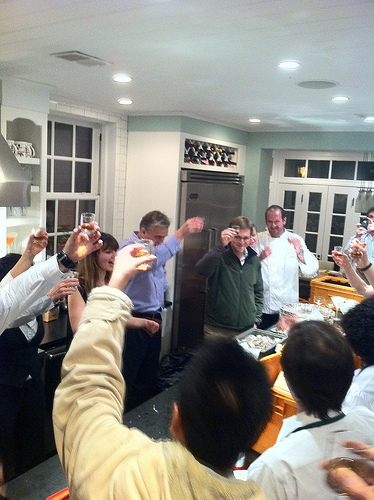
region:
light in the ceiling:
[273, 61, 301, 70]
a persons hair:
[192, 352, 255, 432]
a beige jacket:
[81, 300, 116, 388]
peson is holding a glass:
[80, 211, 93, 231]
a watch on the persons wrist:
[55, 249, 74, 266]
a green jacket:
[214, 266, 260, 322]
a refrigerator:
[184, 184, 242, 219]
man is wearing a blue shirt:
[135, 280, 162, 306]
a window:
[48, 135, 90, 195]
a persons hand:
[329, 249, 352, 269]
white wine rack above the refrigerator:
[182, 136, 243, 175]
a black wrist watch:
[57, 250, 77, 269]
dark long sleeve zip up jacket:
[195, 247, 264, 329]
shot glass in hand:
[135, 240, 154, 260]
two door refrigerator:
[178, 169, 243, 344]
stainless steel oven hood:
[1, 131, 30, 205]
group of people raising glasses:
[13, 212, 371, 490]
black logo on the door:
[188, 193, 200, 199]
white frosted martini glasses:
[329, 295, 355, 322]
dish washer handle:
[44, 345, 64, 360]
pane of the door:
[308, 193, 319, 210]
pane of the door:
[334, 191, 346, 212]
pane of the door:
[331, 216, 344, 233]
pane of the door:
[328, 240, 342, 257]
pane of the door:
[304, 234, 317, 253]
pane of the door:
[286, 190, 296, 209]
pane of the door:
[75, 128, 92, 155]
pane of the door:
[54, 131, 68, 156]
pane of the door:
[70, 165, 95, 192]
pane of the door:
[56, 199, 74, 228]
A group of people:
[1, 191, 372, 498]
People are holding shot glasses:
[2, 180, 370, 498]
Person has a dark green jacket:
[191, 232, 266, 337]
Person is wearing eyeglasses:
[231, 230, 251, 244]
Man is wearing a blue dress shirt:
[114, 229, 186, 315]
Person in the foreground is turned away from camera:
[44, 240, 283, 498]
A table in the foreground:
[0, 299, 373, 498]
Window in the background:
[47, 113, 109, 259]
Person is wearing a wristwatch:
[50, 242, 86, 279]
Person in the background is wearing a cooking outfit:
[243, 201, 326, 330]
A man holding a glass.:
[194, 216, 263, 346]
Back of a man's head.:
[169, 334, 274, 471]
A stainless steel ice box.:
[170, 168, 244, 351]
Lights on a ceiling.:
[111, 72, 372, 124]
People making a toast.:
[0, 205, 373, 498]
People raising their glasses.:
[1, 204, 372, 497]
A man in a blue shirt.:
[118, 210, 204, 411]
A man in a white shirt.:
[256, 203, 319, 315]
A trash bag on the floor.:
[158, 345, 197, 392]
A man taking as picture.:
[344, 207, 372, 273]